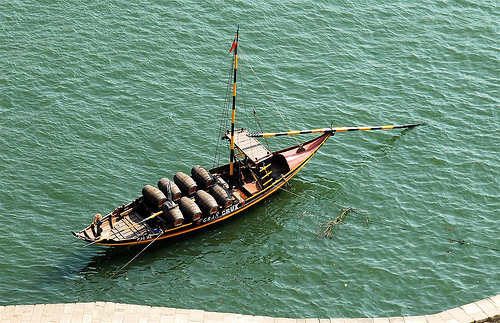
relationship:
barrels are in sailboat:
[142, 160, 238, 232] [60, 114, 354, 264]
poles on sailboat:
[219, 35, 428, 194] [60, 114, 354, 264]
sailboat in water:
[60, 114, 354, 264] [269, 11, 473, 106]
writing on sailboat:
[196, 197, 242, 228] [60, 114, 354, 264]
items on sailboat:
[142, 160, 238, 232] [60, 114, 354, 264]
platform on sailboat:
[102, 204, 161, 243] [60, 114, 354, 264]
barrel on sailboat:
[139, 180, 168, 204] [60, 114, 354, 264]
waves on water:
[293, 31, 490, 94] [269, 11, 473, 106]